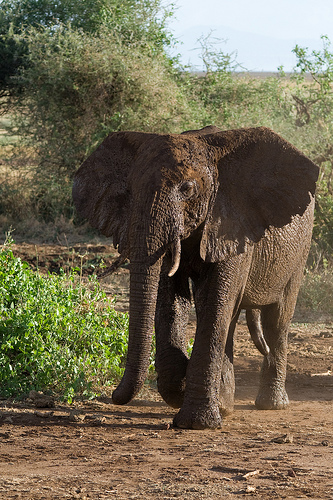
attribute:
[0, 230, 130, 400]
plant — green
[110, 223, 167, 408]
trunk — hanging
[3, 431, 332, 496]
ground — brown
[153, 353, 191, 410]
leg — up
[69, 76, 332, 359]
elephant —   big,  fat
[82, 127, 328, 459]
elephant — wrinkled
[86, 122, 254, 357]
elephant — brown 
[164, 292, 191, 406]
leg — in air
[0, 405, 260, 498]
sand — brown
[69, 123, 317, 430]
elphant — dirty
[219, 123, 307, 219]
ears — BIG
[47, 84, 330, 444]
elephant — big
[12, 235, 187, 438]
vegetation — green 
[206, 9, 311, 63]
cloud — clear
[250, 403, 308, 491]
surface — brown, muddy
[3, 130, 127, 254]
grass — dry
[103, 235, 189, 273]
tusks — short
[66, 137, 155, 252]
ear — wet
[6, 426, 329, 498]
surface —  brown,  muddy 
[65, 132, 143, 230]
ear — BIG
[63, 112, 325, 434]
elephant — huge, muddy, big